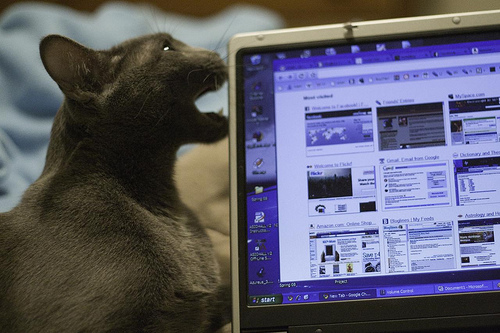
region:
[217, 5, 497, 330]
flat computer screen near cat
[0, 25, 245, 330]
gray cat next to computer screen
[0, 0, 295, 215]
light blue fabric behind cat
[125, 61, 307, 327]
light brown fabric behind cat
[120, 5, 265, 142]
whispers protruding from cat's face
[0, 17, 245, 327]
gray cat hissing near computer screen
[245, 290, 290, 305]
windows start button on computer screen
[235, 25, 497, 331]
black frame around computer screen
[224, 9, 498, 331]
light brown and gray trim around laptop screen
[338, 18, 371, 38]
laptop screen latch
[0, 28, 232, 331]
a gray cat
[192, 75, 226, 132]
open mouth of the cat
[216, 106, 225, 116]
the cat's sharp tooth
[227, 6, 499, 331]
a laptop computer monitor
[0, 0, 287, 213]
a blue blanket behind the cat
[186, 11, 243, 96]
whiskers on the cat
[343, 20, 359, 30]
plastic latch on the computer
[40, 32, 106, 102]
the cat's pointy ear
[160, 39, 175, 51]
the black eye of the cat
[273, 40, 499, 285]
open window on the laptop screen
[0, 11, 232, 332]
furry gray domesticated feline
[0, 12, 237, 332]
grey adult cat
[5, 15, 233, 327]
small furry four legged mammal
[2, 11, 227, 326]
small furry mammal with large ears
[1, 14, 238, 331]
cat vocalizing at unknown person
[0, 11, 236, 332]
cat sitting next to laptop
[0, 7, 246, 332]
cat with grey fur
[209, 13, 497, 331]
laptop screen with icons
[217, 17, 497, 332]
screen of a windows personal computer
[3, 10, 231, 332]
pet with teeth and whiskers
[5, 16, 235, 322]
A gray cat to the left of the computer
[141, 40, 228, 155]
The cat's mouth is open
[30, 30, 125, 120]
The cat's ear is alert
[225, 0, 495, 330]
The computer is on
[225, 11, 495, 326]
Laptop next to the cat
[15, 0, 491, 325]
Nobody shown in the photo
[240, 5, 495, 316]
Windows computer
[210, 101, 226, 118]
The cat's tooth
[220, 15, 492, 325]
The computer's keyboard isn't visible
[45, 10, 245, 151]
The cat is looking up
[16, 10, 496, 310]
cat next to a computer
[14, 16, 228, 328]
dark grey cat meowing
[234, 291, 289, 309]
windows start bar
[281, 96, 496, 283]
many pages open on computer screen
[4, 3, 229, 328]
cat laying on brown blanket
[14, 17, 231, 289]
cat opening its mouth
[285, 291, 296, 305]
google chrome icon on computer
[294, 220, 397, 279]
Amazon.com page preview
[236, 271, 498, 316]
task bar on computer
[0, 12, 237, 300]
cat wanting attention